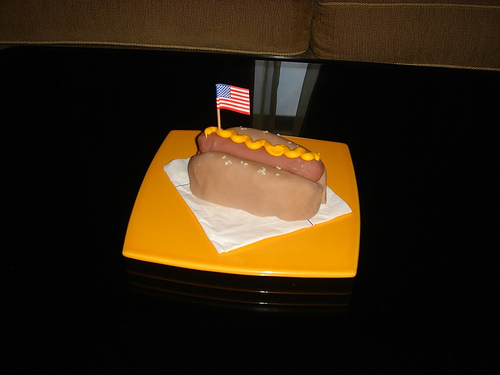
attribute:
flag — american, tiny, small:
[215, 83, 250, 117]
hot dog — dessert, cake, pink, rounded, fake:
[197, 127, 325, 182]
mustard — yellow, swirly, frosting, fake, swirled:
[204, 126, 321, 162]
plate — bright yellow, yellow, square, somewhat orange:
[121, 128, 361, 279]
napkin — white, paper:
[162, 156, 353, 255]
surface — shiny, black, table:
[1, 43, 499, 374]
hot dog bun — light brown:
[188, 126, 329, 221]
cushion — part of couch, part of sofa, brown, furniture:
[0, 1, 315, 59]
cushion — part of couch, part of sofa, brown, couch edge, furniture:
[310, 0, 500, 73]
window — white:
[249, 58, 322, 137]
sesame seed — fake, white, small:
[275, 172, 280, 178]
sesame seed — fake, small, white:
[243, 162, 247, 165]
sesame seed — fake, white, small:
[221, 156, 226, 159]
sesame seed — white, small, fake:
[276, 133, 280, 137]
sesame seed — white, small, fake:
[287, 141, 292, 146]